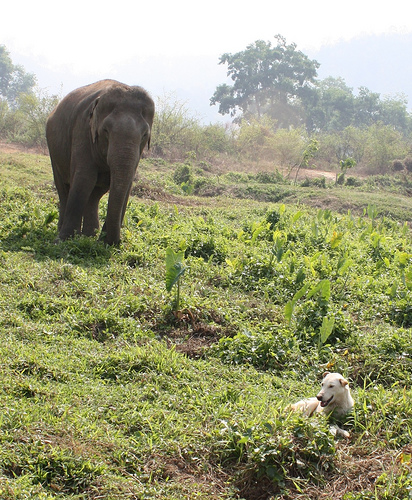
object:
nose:
[317, 396, 323, 401]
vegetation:
[204, 204, 409, 368]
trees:
[209, 34, 321, 138]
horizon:
[314, 7, 411, 85]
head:
[316, 371, 348, 407]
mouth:
[317, 396, 334, 408]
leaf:
[165, 247, 186, 293]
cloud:
[0, 0, 411, 50]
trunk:
[105, 136, 139, 243]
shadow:
[6, 233, 106, 263]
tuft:
[215, 421, 337, 496]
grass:
[0, 156, 412, 500]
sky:
[0, 0, 410, 74]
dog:
[285, 372, 354, 437]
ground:
[0, 173, 412, 500]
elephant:
[46, 79, 155, 249]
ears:
[88, 96, 100, 144]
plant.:
[297, 282, 345, 347]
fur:
[300, 397, 317, 412]